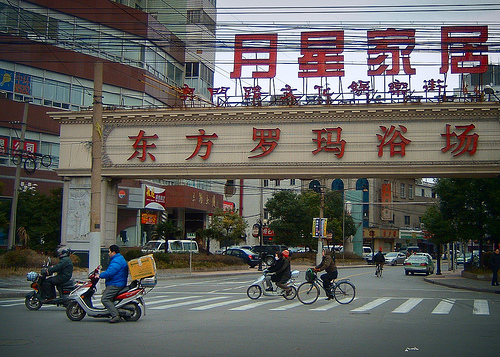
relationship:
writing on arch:
[121, 125, 486, 162] [115, 123, 482, 163]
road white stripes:
[229, 293, 493, 320] [230, 292, 494, 321]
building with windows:
[6, 5, 184, 111] [1, 1, 184, 106]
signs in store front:
[138, 184, 172, 240] [139, 181, 170, 229]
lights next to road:
[305, 178, 333, 254] [310, 180, 331, 251]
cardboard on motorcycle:
[128, 253, 157, 281] [68, 263, 162, 325]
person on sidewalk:
[486, 245, 499, 287] [488, 245, 500, 288]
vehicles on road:
[380, 248, 437, 275] [382, 249, 439, 278]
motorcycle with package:
[68, 252, 163, 324] [65, 252, 162, 325]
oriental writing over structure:
[223, 21, 493, 83] [224, 22, 492, 83]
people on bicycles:
[241, 244, 359, 310] [244, 243, 360, 310]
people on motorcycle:
[24, 245, 160, 327] [68, 263, 162, 325]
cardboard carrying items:
[126, 250, 161, 285] [126, 251, 161, 284]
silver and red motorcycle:
[19, 241, 160, 327] [68, 263, 162, 325]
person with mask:
[260, 245, 284, 274] [267, 250, 285, 270]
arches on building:
[304, 177, 371, 197] [304, 176, 372, 194]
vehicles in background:
[141, 237, 260, 270] [143, 236, 259, 271]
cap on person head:
[51, 243, 73, 263] [51, 239, 72, 260]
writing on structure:
[115, 126, 486, 158] [116, 125, 483, 158]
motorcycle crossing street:
[68, 263, 162, 325] [23, 239, 161, 323]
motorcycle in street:
[68, 263, 162, 325] [23, 239, 161, 323]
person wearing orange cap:
[276, 248, 292, 262] [278, 246, 292, 262]